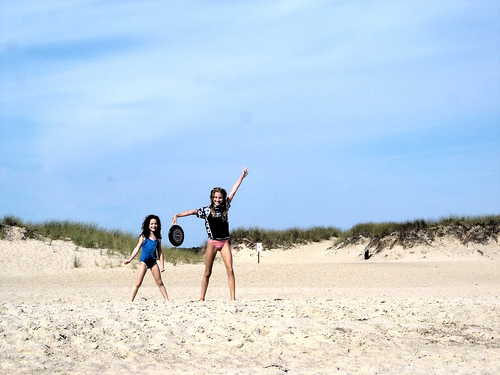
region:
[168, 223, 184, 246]
black frisbee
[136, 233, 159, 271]
blue one piece swimsuit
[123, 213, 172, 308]
younger girl on the beach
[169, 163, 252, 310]
bigger girl on the beach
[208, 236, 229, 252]
pink swimsuit bottom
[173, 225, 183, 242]
white logo on a frisbee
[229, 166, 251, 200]
girl's arm in the air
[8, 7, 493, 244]
blue sky with white clouds stretched thin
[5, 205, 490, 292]
bushy green grass growing on top of dunes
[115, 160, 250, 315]
two girls smiling and posing at the beach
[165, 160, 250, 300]
girl holding black frisbee in one hand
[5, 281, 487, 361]
small indentations all over the sand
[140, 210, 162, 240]
girl with long and thick black hair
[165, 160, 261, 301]
girl with one arm lifted toward the sky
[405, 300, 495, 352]
small black objects scattered over sand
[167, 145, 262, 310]
a young lady holding a black frisbee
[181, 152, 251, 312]
a young girl holding her arm out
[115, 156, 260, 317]
a young girl standing with an older girl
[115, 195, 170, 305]
a young girl wearing a blue bathing suit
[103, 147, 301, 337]
2 little girls posing for a picture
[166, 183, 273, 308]
this is a girl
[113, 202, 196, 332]
this is a girl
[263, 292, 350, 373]
the sand is tan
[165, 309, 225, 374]
the sand is tan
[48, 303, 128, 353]
the sand is tan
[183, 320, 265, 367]
the sand is tan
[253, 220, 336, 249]
this is grass at the edge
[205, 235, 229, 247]
The pink bikini bottom the girl is wearing.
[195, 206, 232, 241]
The black shirt the girl is wearing.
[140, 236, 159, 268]
The blue and black bathing suit the girl is wearing.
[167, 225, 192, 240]
The black frisbee in the air.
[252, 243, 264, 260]
The white sign in the distance.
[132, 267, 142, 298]
The left leg of the girl in the back.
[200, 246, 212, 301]
The left leg of the girl in the front.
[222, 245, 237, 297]
The right leg of the girl in the front.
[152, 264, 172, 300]
The right leg of the girl in the back.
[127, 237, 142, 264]
The left arm of the girl in the back.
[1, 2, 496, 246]
cloud cover in sky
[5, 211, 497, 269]
grass on sand bluff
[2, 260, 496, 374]
sandy surface of beach